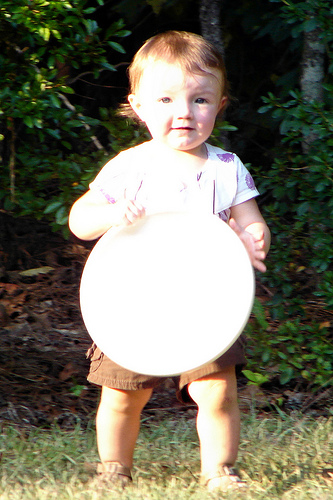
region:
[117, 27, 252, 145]
head of a kid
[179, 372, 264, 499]
leg of a kid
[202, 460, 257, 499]
sandal on the kid's foot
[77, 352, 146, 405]
brown shorts on the kid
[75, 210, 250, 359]
white Frisbee in kid's hand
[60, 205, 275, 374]
round Frisbee in the photo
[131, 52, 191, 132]
light hitting the kid's face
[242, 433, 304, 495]
grass on the ground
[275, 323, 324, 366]
leaves behind the kid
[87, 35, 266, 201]
kid looking at the camera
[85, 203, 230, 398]
the frisbee is white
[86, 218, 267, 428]
the frisbee is white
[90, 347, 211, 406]
the short is brown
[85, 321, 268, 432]
the short is brown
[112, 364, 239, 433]
the short is brown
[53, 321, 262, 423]
the short is brown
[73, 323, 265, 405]
the short is brown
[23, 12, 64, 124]
The leaves are short and green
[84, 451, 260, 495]
The feet of the baby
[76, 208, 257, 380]
The frisbee is the color white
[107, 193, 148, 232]
The hand of the baby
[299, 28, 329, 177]
The tree trunk is the color brown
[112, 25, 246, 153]
The head of the baby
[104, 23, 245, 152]
The baby has brown hair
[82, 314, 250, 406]
The baby is wearing brown shorts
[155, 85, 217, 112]
The eyes of the baby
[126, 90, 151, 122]
The ear of the baby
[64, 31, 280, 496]
A baby holding a frisbee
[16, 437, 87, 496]
The grass is short and green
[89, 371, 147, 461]
The leg of the baby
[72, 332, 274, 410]
The shorts of the baby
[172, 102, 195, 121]
The nose of the baby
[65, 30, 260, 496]
A toddler with a frisbee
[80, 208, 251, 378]
A white frisbee.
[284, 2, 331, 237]
A birch tree in the woods.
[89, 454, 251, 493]
A pair of brown toddler's shoes.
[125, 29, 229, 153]
A child posing for a picture.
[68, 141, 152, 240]
A child's hand holding a frisbee.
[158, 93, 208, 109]
A toddler's blue eyes.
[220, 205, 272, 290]
A child's hand about to grip a frisbee.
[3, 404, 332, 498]
Tall green grass.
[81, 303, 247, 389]
A pair of brown child's shorts.